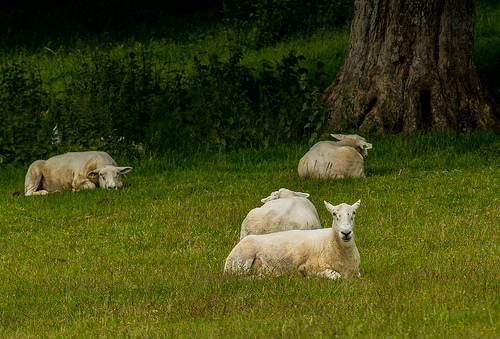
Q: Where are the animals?
A: On the grass.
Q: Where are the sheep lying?
A: In a field.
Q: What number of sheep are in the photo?
A: 4.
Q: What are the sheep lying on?
A: Grass.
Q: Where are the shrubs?
A: Next to the large tree trunk.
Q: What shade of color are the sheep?
A: Beige and white.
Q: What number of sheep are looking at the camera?
A: 1.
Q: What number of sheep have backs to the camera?
A: 2.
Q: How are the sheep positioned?
A: Lying on stomachs.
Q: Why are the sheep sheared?
A: To take wool.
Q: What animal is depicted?
A: Sheep.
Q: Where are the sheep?
A: Green pasture.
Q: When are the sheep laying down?
A: During the daylight.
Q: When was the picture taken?
A: Daytime.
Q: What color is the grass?
A: Green.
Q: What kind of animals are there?
A: Sheep.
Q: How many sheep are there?
A: Four.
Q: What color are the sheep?
A: White.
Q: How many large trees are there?
A: One.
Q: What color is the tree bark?
A: Brown.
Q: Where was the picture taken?
A: In a meadow.